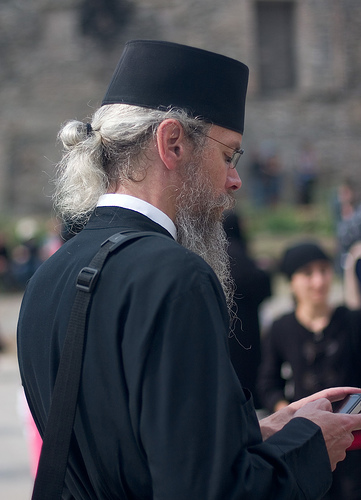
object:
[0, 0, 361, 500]
photo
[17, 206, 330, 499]
suit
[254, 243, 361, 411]
woman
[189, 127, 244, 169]
glasses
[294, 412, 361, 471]
hand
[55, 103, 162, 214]
style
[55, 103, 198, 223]
hair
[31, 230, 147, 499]
strap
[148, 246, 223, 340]
shoulder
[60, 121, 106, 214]
pony tail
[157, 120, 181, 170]
ear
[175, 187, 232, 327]
beard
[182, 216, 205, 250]
grey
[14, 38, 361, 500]
man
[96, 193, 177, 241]
collar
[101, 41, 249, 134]
cap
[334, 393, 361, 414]
cell phone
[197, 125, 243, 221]
face